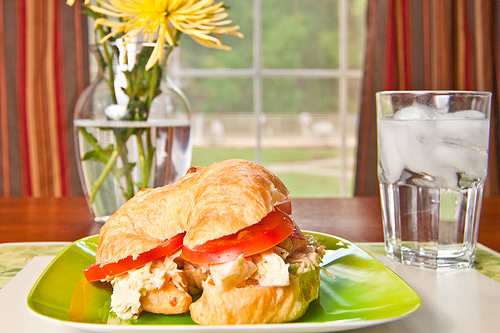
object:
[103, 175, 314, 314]
sandwich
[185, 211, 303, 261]
tomato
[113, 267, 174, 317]
chicken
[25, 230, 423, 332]
plate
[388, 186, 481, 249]
water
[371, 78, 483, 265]
glass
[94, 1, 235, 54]
flowers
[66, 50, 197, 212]
vase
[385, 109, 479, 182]
ice cubes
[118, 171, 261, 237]
croissant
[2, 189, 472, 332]
table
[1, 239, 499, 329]
placemat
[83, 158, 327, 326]
lunch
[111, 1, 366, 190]
window